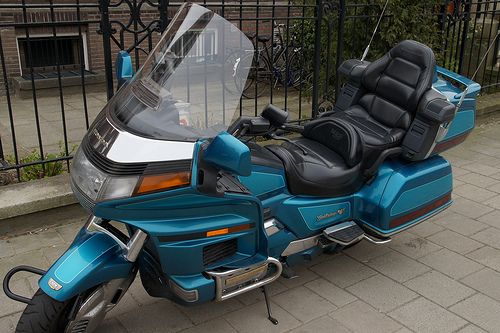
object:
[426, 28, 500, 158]
antenna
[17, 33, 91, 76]
window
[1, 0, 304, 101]
building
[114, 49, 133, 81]
mirror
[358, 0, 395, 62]
radio antenna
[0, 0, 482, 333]
motorcycle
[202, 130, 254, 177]
mirror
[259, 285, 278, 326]
kickstand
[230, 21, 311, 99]
bicycle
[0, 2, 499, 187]
fence